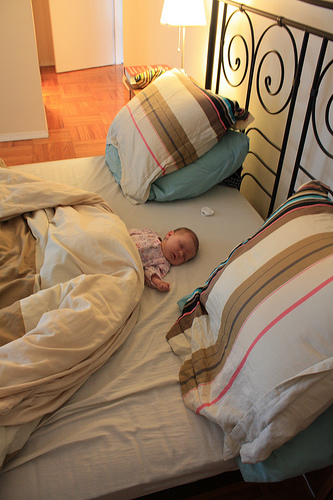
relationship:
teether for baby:
[202, 206, 216, 216] [122, 220, 206, 296]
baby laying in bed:
[122, 220, 206, 296] [2, 0, 332, 477]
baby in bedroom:
[122, 220, 206, 296] [2, 1, 332, 499]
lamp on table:
[159, 0, 211, 68] [120, 63, 181, 105]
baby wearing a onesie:
[122, 220, 206, 296] [125, 226, 170, 282]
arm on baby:
[149, 270, 170, 294] [122, 220, 206, 296]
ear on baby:
[163, 228, 177, 241] [122, 220, 206, 296]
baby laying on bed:
[122, 220, 206, 296] [2, 0, 332, 477]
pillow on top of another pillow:
[91, 64, 254, 202] [103, 135, 257, 206]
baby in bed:
[122, 220, 206, 296] [2, 0, 332, 477]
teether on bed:
[202, 206, 216, 216] [2, 0, 332, 477]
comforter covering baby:
[1, 167, 142, 466] [122, 220, 206, 296]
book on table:
[118, 62, 171, 87] [120, 63, 181, 105]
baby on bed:
[122, 220, 206, 296] [2, 0, 332, 477]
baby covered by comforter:
[122, 220, 206, 296] [1, 167, 142, 466]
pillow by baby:
[104, 64, 254, 202] [122, 220, 206, 296]